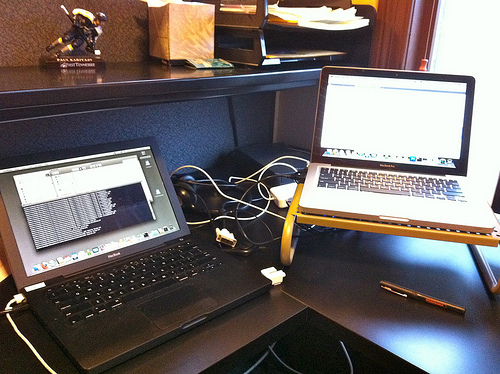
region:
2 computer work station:
[2, 3, 497, 372]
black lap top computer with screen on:
[5, 135, 271, 369]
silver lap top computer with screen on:
[296, 60, 498, 228]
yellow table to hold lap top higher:
[278, 179, 498, 275]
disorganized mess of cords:
[177, 155, 289, 246]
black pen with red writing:
[378, 273, 464, 318]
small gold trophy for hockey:
[40, 0, 111, 86]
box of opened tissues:
[149, 7, 220, 64]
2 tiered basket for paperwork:
[220, 0, 382, 71]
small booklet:
[182, 53, 236, 69]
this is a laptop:
[310, 67, 491, 222]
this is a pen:
[370, 266, 462, 315]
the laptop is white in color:
[327, 190, 392, 215]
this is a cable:
[1, 307, 50, 360]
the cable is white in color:
[18, 336, 41, 356]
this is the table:
[290, 250, 348, 305]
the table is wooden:
[303, 262, 338, 299]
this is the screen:
[29, 182, 130, 214]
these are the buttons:
[89, 272, 159, 297]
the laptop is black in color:
[212, 273, 240, 290]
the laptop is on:
[340, 82, 443, 149]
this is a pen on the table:
[371, 280, 469, 305]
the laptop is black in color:
[148, 257, 203, 328]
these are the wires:
[223, 167, 269, 227]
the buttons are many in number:
[113, 259, 142, 288]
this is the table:
[306, 263, 348, 310]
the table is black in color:
[311, 248, 357, 302]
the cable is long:
[11, 318, 30, 357]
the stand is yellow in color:
[281, 213, 306, 253]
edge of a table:
[368, 356, 380, 368]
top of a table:
[349, 308, 360, 327]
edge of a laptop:
[229, 276, 256, 311]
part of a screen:
[33, 274, 53, 325]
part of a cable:
[281, 358, 300, 363]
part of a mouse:
[144, 268, 161, 317]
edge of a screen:
[71, 217, 92, 268]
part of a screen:
[54, 230, 87, 281]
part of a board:
[267, 223, 283, 240]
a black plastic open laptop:
[2, 140, 279, 360]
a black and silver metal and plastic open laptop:
[296, 62, 493, 234]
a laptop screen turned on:
[4, 151, 184, 273]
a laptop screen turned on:
[321, 73, 465, 168]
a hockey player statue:
[40, 6, 112, 72]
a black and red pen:
[378, 275, 466, 321]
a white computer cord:
[5, 288, 52, 371]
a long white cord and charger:
[170, 153, 309, 245]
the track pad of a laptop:
[135, 287, 214, 326]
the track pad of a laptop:
[372, 191, 416, 220]